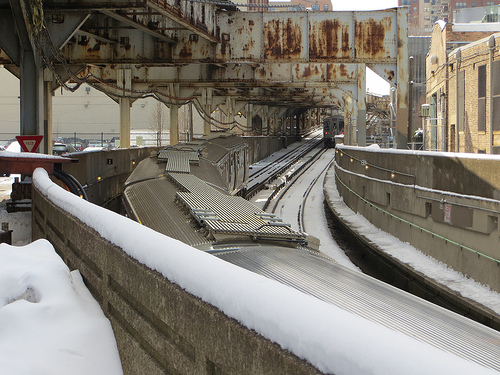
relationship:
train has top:
[321, 114, 344, 147] [325, 111, 345, 120]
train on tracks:
[321, 114, 344, 147] [241, 128, 336, 254]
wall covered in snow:
[32, 167, 499, 373] [0, 235, 123, 374]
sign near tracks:
[16, 134, 45, 153] [241, 128, 336, 254]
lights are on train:
[324, 129, 345, 136] [321, 114, 344, 147]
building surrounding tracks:
[423, 19, 499, 154] [241, 128, 336, 254]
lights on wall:
[333, 149, 396, 178] [333, 144, 499, 291]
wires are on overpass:
[36, 55, 283, 134] [1, 0, 409, 211]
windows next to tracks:
[455, 61, 499, 132] [241, 128, 336, 254]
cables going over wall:
[52, 168, 88, 202] [32, 167, 499, 373]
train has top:
[117, 134, 500, 374] [119, 129, 498, 373]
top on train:
[325, 111, 345, 120] [321, 114, 344, 147]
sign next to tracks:
[16, 134, 45, 153] [241, 128, 336, 254]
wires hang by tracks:
[36, 55, 283, 134] [241, 128, 336, 254]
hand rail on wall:
[335, 147, 415, 181] [333, 144, 499, 291]